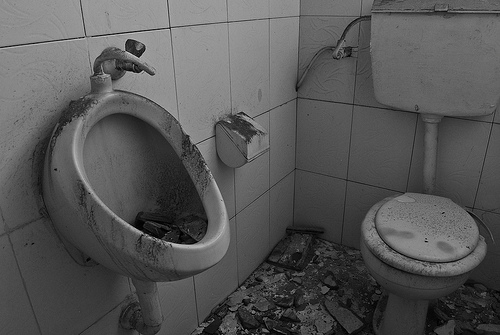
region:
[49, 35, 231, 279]
urinal filled with crumbling rocks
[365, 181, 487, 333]
filthy white porcelain toilet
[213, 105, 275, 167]
white metal toilet paper holder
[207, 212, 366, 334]
debris all over tile floor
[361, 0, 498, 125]
white porcelain toilet tank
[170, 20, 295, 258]
white tiles on wall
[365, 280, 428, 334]
toilet pedestal covered in soot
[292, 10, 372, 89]
plumbing pipes coming through wall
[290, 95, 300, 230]
black grout in white tile wall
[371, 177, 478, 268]
crooked toilet seat cover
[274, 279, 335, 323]
broken tiles on the floor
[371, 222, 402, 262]
dirt on the toilet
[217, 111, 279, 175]
tissue holder on the wall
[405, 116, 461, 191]
pipe coming from the water tank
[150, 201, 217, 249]
broken bricks in the urinal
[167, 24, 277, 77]
square tiles on the wall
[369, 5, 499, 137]
water tank on the wall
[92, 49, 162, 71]
water hose on the urinal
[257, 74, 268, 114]
a stain on the wall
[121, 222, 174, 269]
feces on the urinal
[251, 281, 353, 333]
Broken pieces of the bathroom on the floor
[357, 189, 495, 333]
Small toilet that is dirty and broken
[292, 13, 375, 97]
Hose to transport water from outside to toilet tank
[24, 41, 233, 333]
Broken dirt urinal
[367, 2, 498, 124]
High tank on toilet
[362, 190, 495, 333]
Bottom dirty white base of toilet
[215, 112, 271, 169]
Little metal thing on bathroom wall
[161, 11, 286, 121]
Tiles on bathroom wall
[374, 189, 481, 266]
Dirty toilet seat lid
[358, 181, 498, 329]
white dirty round toilet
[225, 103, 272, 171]
square toilet paper holder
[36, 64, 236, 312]
large round mens urinal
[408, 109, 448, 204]
pipe from toilet to toilet bowl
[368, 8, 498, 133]
square toilet water resevoir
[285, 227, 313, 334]
pieces of debree from construction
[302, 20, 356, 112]
wire from wall to water resevoir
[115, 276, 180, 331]
pipe connecting urinal to water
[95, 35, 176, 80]
a black knob for flushing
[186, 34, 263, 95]
white bathroom wall tiles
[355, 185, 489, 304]
this is a toilet sink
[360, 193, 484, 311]
the toilet sink is closed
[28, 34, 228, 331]
the urinal sink is dirty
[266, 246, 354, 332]
the room has dirt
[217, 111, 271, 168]
the tissue paper holder is dirsty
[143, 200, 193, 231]
dust are inside the urinal sink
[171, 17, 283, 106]
the tiles are dusty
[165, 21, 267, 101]
the ties are arranged in a square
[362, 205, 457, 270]
the toilet sink is white in color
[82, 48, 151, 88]
the pipe is folded